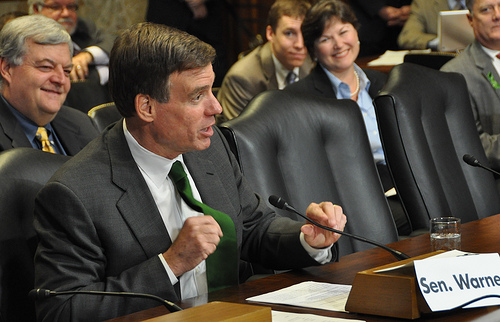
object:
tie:
[168, 160, 240, 294]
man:
[32, 21, 348, 322]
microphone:
[268, 195, 411, 261]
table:
[106, 213, 500, 322]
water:
[431, 233, 461, 252]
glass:
[429, 216, 462, 251]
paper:
[245, 281, 353, 314]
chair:
[216, 89, 399, 274]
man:
[0, 14, 101, 157]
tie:
[36, 126, 56, 153]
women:
[281, 0, 413, 236]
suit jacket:
[214, 41, 314, 125]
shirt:
[122, 118, 204, 301]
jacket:
[32, 116, 340, 322]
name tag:
[413, 253, 499, 312]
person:
[398, 1, 466, 50]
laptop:
[435, 10, 474, 52]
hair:
[108, 22, 217, 118]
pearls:
[351, 71, 360, 96]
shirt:
[319, 62, 386, 166]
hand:
[158, 215, 224, 272]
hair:
[1, 13, 75, 67]